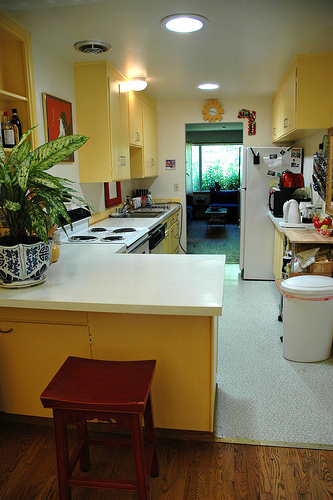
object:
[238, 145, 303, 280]
refrigerator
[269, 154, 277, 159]
pictures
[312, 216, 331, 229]
apple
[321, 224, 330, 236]
banana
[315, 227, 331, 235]
bowl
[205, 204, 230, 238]
table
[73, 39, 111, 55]
silver fan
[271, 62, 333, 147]
cabinet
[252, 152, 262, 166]
pictures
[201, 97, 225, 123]
clock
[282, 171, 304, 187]
coffee maker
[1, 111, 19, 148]
bottle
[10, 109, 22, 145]
bottle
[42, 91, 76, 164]
frame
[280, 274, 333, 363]
garbage can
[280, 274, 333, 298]
white lid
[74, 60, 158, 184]
cabinets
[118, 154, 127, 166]
handles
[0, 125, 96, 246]
plant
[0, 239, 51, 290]
pot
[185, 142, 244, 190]
window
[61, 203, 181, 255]
stove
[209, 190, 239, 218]
couch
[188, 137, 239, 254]
livingroom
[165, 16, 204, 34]
ceiling light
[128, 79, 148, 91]
ceiling light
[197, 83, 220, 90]
ceiling light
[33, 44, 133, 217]
wall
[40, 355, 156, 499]
chair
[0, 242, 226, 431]
counter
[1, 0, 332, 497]
kitchen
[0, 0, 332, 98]
ceiling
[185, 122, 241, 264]
doorway